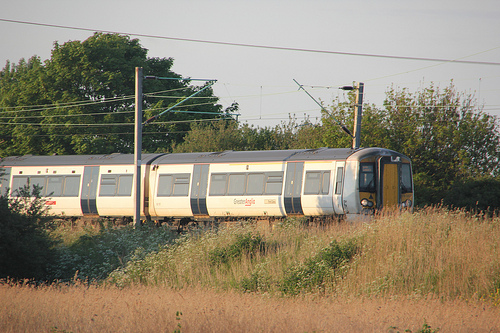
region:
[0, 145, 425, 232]
white and black train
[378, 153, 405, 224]
yellow door on the front of a train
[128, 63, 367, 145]
wires crossing over a train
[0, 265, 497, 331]
brown dry looking grass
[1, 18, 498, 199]
green trees near the train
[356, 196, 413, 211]
headlights on the train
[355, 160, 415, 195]
front windows on the train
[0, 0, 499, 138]
grey colored sky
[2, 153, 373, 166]
grey top on the train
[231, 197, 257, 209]
words on the side of the train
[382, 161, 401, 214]
the yellow door on the train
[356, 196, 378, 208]
the lights on the train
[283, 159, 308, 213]
the door on the side of the train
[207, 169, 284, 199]
the row of windows on the train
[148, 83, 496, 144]
the wires hanging above the train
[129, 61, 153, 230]
the post on the side of the tracks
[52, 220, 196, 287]
the flowers on the side of the hill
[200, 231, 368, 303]
the green bushes in the brush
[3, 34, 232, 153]
the trees behind the power lines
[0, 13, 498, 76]
the power line hanging above the train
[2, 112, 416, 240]
train passing by a field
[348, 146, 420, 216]
front of a train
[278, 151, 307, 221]
door to a train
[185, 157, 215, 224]
door to a train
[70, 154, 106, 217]
door to the rear passenger cargo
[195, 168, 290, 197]
windows of a train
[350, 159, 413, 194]
front windshield of train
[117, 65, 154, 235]
a steel pillar on ground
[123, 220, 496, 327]
a dry grassy field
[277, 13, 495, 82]
sky with no cloud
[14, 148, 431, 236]
grey and beige train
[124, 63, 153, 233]
silver power pole in front of train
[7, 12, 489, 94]
single power line running above train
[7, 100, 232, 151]
group of power lines above train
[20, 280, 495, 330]
dry wheat colored vegetation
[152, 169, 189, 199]
two pane window on side of train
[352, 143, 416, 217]
train with yellow door on front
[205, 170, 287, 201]
four pane window on train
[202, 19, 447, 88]
blueish grey colored sky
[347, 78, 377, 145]
silver power pole behind train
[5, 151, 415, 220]
a train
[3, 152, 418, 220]
a blue, white and yellow train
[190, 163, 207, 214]
the door of the train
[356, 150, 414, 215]
the yellow front of the train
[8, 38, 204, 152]
a large tree in the back ground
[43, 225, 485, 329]
weeds in front of the train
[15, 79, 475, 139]
wires above the train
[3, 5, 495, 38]
the grey sky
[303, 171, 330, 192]
the window of the train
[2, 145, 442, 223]
a tram train